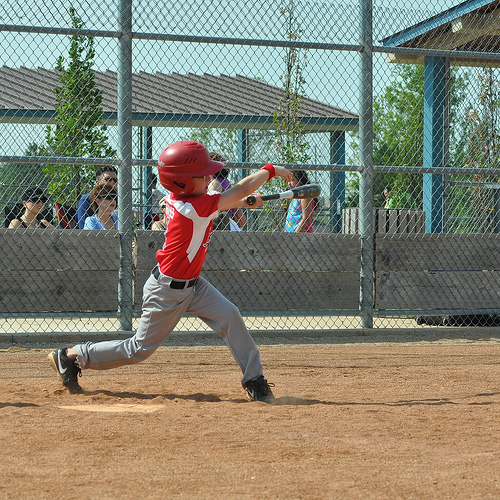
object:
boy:
[48, 138, 294, 404]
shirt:
[153, 193, 222, 281]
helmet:
[155, 140, 225, 195]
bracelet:
[260, 162, 278, 180]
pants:
[73, 268, 262, 380]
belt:
[151, 265, 203, 290]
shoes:
[46, 344, 278, 405]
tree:
[43, 6, 117, 209]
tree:
[371, 63, 465, 209]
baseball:
[245, 181, 323, 205]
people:
[7, 154, 318, 232]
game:
[0, 139, 496, 496]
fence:
[0, 0, 498, 333]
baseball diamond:
[16, 345, 484, 499]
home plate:
[54, 401, 165, 415]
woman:
[9, 185, 61, 230]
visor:
[18, 187, 49, 200]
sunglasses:
[30, 196, 47, 205]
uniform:
[78, 193, 263, 381]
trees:
[10, 8, 497, 203]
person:
[84, 185, 119, 228]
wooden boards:
[0, 231, 498, 313]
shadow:
[69, 386, 498, 408]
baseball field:
[0, 340, 499, 498]